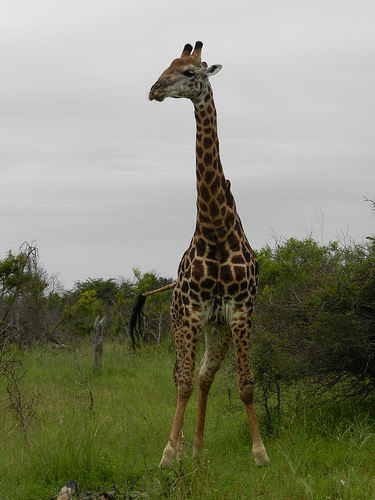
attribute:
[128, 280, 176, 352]
tail — swinging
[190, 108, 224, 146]
neck — long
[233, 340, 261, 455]
leg — long, strong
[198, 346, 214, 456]
leg — long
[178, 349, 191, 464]
leg — long, strong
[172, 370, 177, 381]
leg — long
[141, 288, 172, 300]
tail — black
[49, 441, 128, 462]
grass — green, tall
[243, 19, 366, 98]
sky — gray, cloudy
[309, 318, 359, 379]
bush — green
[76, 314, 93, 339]
bush — green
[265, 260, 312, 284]
bush — green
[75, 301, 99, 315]
bush — green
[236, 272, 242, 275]
fur — brown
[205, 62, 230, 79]
ear — white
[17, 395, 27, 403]
branch — bare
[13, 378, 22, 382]
branch — bare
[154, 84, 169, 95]
muzzle — close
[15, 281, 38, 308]
bush — green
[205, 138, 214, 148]
spot — brown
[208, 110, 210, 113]
spot — brown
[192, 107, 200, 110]
spot — brown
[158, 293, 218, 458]
leg — long 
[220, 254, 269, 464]
leg — long 